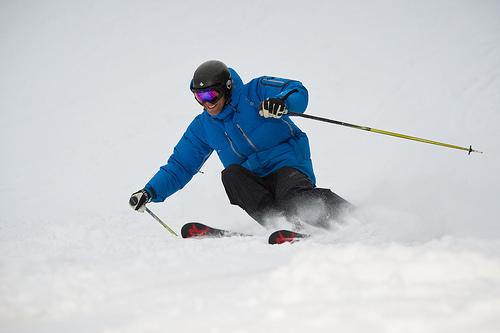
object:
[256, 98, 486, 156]
ski pole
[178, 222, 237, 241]
skis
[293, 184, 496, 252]
snow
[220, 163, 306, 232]
leg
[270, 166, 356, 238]
leg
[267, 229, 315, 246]
ski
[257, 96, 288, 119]
hand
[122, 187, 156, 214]
hand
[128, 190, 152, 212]
hand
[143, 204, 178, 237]
ski pole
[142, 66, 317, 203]
coat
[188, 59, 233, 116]
helmet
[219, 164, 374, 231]
pants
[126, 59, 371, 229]
man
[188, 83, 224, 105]
goggles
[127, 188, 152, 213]
gloves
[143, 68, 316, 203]
jacket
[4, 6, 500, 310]
slope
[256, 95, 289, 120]
glove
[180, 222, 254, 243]
bottom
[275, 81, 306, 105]
lettering